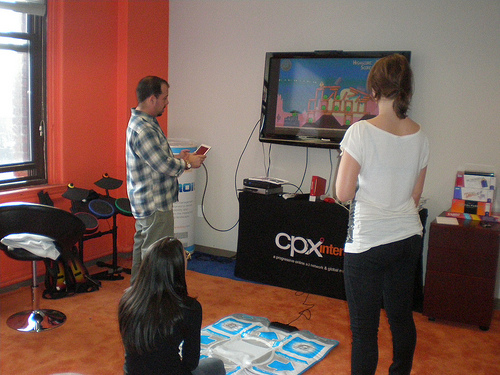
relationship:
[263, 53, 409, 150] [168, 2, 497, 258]
tv on wall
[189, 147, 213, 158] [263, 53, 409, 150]
controller of tv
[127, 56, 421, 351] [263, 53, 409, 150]
people standing in front of tv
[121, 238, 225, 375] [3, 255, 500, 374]
woman sitting on floor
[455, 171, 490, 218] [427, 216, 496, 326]
box on cart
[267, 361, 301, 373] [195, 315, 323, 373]
arrow on mat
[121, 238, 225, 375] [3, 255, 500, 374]
woman sitting on ground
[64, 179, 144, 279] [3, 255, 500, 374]
drumset on carpet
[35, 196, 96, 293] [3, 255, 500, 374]
guitars on carpet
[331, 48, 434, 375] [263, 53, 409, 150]
people watching tv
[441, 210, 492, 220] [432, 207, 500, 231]
books on counter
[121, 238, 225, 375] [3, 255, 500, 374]
girl on floor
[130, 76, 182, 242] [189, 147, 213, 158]
man holding controller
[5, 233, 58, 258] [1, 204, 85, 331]
white shirt sitting in black chair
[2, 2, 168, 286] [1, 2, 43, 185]
wall next to window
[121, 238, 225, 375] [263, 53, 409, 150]
woman looking at tv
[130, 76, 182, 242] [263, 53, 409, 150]
man looking at tv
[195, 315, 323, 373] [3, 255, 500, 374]
cloth on floor